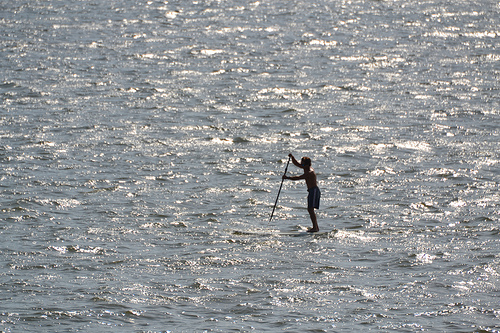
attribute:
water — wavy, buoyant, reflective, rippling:
[1, 1, 499, 331]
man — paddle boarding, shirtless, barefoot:
[281, 152, 323, 233]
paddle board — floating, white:
[277, 224, 365, 239]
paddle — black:
[271, 154, 290, 218]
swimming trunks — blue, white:
[306, 184, 321, 211]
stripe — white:
[311, 185, 318, 209]